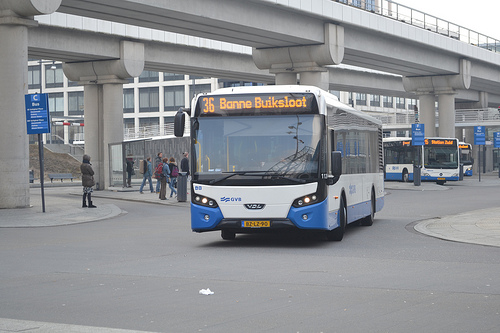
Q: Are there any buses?
A: Yes, there is a bus.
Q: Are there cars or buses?
A: Yes, there is a bus.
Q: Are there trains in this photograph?
A: No, there are no trains.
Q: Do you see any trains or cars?
A: No, there are no trains or cars.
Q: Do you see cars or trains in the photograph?
A: No, there are no trains or cars.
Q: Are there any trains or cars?
A: No, there are no trains or cars.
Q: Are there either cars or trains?
A: No, there are no trains or cars.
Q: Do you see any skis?
A: No, there are no skis.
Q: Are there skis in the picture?
A: No, there are no skis.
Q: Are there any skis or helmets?
A: No, there are no skis or helmets.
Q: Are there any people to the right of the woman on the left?
A: Yes, there is a person to the right of the woman.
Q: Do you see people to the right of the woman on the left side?
A: Yes, there is a person to the right of the woman.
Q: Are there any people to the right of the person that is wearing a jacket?
A: Yes, there is a person to the right of the woman.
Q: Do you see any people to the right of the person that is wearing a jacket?
A: Yes, there is a person to the right of the woman.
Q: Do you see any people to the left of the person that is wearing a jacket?
A: No, the person is to the right of the woman.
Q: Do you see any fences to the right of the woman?
A: No, there is a person to the right of the woman.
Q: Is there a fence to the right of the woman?
A: No, there is a person to the right of the woman.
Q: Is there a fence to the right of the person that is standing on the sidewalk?
A: No, there is a person to the right of the woman.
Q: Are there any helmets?
A: No, there are no helmets.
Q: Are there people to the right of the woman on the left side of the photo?
A: Yes, there is a person to the right of the woman.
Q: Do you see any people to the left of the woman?
A: No, the person is to the right of the woman.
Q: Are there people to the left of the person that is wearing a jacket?
A: No, the person is to the right of the woman.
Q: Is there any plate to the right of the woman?
A: No, there is a person to the right of the woman.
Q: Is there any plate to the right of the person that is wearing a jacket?
A: No, there is a person to the right of the woman.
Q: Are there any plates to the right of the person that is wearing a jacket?
A: No, there is a person to the right of the woman.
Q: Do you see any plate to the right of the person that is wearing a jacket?
A: No, there is a person to the right of the woman.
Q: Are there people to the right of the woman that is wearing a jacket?
A: Yes, there is a person to the right of the woman.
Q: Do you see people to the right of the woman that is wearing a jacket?
A: Yes, there is a person to the right of the woman.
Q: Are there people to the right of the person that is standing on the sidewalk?
A: Yes, there is a person to the right of the woman.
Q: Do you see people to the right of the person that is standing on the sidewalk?
A: Yes, there is a person to the right of the woman.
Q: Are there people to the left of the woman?
A: No, the person is to the right of the woman.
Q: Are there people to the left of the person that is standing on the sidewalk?
A: No, the person is to the right of the woman.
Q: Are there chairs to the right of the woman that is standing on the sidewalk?
A: No, there is a person to the right of the woman.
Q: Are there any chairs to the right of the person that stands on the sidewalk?
A: No, there is a person to the right of the woman.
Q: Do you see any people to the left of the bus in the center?
A: Yes, there is a person to the left of the bus.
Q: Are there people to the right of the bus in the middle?
A: No, the person is to the left of the bus.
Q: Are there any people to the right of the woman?
A: Yes, there is a person to the right of the woman.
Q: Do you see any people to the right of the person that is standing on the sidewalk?
A: Yes, there is a person to the right of the woman.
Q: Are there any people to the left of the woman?
A: No, the person is to the right of the woman.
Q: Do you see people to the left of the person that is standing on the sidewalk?
A: No, the person is to the right of the woman.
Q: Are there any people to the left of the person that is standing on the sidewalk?
A: No, the person is to the right of the woman.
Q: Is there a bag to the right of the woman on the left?
A: No, there is a person to the right of the woman.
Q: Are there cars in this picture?
A: No, there are no cars.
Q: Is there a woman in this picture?
A: Yes, there is a woman.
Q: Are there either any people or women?
A: Yes, there is a woman.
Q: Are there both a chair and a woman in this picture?
A: No, there is a woman but no chairs.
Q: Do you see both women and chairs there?
A: No, there is a woman but no chairs.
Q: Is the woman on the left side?
A: Yes, the woman is on the left of the image.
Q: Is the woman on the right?
A: No, the woman is on the left of the image.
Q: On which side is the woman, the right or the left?
A: The woman is on the left of the image.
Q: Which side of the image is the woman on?
A: The woman is on the left of the image.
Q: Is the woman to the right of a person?
A: No, the woman is to the left of a person.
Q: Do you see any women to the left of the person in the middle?
A: Yes, there is a woman to the left of the person.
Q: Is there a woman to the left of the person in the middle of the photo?
A: Yes, there is a woman to the left of the person.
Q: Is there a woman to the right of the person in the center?
A: No, the woman is to the left of the person.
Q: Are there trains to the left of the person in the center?
A: No, there is a woman to the left of the person.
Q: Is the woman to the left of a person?
A: Yes, the woman is to the left of a person.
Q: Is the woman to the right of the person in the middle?
A: No, the woman is to the left of the person.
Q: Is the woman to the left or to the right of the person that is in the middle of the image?
A: The woman is to the left of the person.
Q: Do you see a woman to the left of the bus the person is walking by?
A: Yes, there is a woman to the left of the bus.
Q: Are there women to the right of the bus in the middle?
A: No, the woman is to the left of the bus.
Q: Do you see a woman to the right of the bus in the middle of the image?
A: No, the woman is to the left of the bus.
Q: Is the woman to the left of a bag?
A: No, the woman is to the left of the bus.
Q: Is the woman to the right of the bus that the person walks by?
A: No, the woman is to the left of the bus.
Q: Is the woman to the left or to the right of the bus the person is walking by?
A: The woman is to the left of the bus.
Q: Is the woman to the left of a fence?
A: No, the woman is to the left of a person.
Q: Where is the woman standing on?
A: The woman is standing on the sidewalk.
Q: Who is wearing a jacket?
A: The woman is wearing a jacket.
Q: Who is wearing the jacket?
A: The woman is wearing a jacket.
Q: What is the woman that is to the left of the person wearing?
A: The woman is wearing a jacket.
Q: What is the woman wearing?
A: The woman is wearing a jacket.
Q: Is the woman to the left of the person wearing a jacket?
A: Yes, the woman is wearing a jacket.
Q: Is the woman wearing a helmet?
A: No, the woman is wearing a jacket.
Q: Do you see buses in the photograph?
A: Yes, there is a bus.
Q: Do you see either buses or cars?
A: Yes, there is a bus.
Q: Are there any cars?
A: No, there are no cars.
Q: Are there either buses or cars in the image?
A: Yes, there is a bus.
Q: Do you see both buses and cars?
A: No, there is a bus but no cars.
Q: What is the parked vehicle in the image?
A: The vehicle is a bus.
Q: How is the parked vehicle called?
A: The vehicle is a bus.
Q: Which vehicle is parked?
A: The vehicle is a bus.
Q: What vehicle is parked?
A: The vehicle is a bus.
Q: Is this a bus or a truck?
A: This is a bus.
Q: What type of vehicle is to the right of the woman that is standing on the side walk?
A: The vehicle is a bus.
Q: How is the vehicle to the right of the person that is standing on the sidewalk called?
A: The vehicle is a bus.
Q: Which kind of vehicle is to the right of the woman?
A: The vehicle is a bus.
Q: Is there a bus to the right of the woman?
A: Yes, there is a bus to the right of the woman.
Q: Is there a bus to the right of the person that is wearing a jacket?
A: Yes, there is a bus to the right of the woman.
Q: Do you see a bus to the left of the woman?
A: No, the bus is to the right of the woman.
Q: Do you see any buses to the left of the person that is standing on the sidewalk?
A: No, the bus is to the right of the woman.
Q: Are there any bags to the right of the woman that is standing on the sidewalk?
A: No, there is a bus to the right of the woman.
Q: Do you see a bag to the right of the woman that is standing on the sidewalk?
A: No, there is a bus to the right of the woman.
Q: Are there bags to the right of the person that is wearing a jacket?
A: No, there is a bus to the right of the woman.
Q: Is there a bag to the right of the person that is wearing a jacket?
A: No, there is a bus to the right of the woman.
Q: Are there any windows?
A: Yes, there is a window.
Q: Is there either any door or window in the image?
A: Yes, there is a window.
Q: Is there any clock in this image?
A: No, there are no clocks.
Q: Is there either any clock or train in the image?
A: No, there are no clocks or trains.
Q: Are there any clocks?
A: No, there are no clocks.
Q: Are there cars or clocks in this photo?
A: No, there are no clocks or cars.